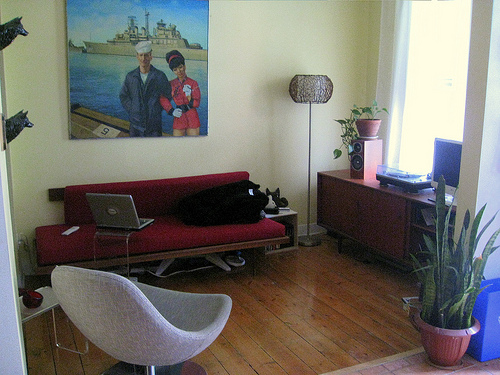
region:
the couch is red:
[19, 147, 304, 284]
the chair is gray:
[48, 243, 233, 373]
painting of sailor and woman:
[103, 34, 203, 129]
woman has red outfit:
[160, 79, 203, 136]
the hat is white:
[115, 30, 169, 60]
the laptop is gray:
[66, 180, 163, 241]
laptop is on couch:
[78, 187, 163, 238]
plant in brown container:
[398, 174, 495, 358]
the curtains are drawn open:
[375, 1, 490, 203]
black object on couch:
[170, 157, 320, 229]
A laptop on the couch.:
[76, 185, 163, 245]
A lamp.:
[275, 60, 336, 255]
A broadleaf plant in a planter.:
[395, 181, 490, 366]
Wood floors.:
[261, 270, 373, 356]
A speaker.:
[335, 135, 380, 180]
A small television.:
[415, 127, 470, 197]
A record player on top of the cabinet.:
[370, 156, 430, 198]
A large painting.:
[46, 0, 221, 136]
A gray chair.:
[42, 260, 232, 370]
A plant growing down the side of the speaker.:
[326, 96, 391, 171]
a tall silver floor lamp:
[285, 72, 337, 249]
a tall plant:
[404, 205, 497, 364]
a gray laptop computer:
[82, 186, 157, 229]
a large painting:
[62, 0, 212, 139]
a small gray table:
[16, 285, 90, 353]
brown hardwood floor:
[22, 232, 441, 373]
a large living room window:
[390, 0, 470, 171]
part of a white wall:
[452, 0, 497, 276]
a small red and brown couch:
[33, 166, 284, 273]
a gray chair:
[39, 262, 234, 374]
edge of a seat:
[238, 238, 248, 241]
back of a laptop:
[106, 212, 137, 223]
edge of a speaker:
[363, 145, 365, 163]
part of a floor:
[214, 319, 232, 351]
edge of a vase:
[430, 330, 440, 336]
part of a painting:
[151, 113, 164, 128]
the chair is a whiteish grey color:
[44, 262, 253, 367]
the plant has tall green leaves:
[421, 172, 484, 319]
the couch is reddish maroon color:
[34, 167, 304, 265]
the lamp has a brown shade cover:
[281, 62, 338, 259]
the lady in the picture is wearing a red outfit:
[162, 41, 206, 136]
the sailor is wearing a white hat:
[114, 37, 166, 74]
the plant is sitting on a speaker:
[334, 100, 396, 192]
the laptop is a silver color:
[78, 185, 160, 239]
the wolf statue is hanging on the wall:
[3, 85, 33, 153]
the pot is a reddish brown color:
[404, 300, 489, 374]